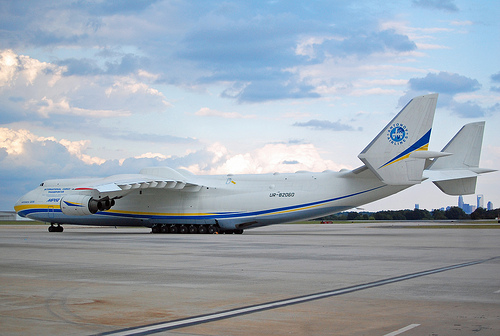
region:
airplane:
[29, 151, 368, 241]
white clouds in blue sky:
[5, 10, 67, 52]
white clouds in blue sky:
[16, 45, 90, 134]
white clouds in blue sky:
[13, 103, 97, 169]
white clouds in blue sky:
[98, 110, 184, 175]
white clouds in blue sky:
[115, 42, 195, 92]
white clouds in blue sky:
[213, 19, 303, 90]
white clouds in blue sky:
[200, 101, 273, 143]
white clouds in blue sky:
[251, 87, 353, 155]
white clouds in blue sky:
[299, 14, 419, 71]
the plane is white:
[17, 104, 493, 264]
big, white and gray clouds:
[69, 29, 368, 191]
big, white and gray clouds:
[132, 114, 294, 196]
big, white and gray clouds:
[22, 67, 133, 223]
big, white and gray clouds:
[286, 28, 463, 117]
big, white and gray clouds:
[43, 45, 141, 134]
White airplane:
[11, 95, 451, 237]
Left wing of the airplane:
[65, 179, 215, 200]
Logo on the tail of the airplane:
[385, 122, 409, 143]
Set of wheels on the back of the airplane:
[148, 222, 245, 237]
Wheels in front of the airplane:
[44, 221, 65, 235]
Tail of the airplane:
[341, 93, 496, 204]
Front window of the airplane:
[37, 181, 47, 189]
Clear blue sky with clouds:
[1, 3, 498, 227]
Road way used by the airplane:
[1, 198, 496, 335]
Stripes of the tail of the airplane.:
[380, 122, 434, 169]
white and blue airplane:
[21, 96, 353, 240]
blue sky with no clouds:
[10, 13, 95, 77]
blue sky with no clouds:
[6, 53, 89, 120]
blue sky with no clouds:
[24, 115, 116, 176]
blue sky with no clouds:
[116, 10, 203, 63]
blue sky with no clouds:
[141, 101, 231, 132]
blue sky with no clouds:
[193, 10, 311, 62]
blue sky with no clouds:
[217, 96, 296, 154]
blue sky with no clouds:
[320, 92, 360, 167]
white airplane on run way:
[30, 110, 376, 252]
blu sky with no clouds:
[7, 12, 117, 87]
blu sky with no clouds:
[19, 65, 88, 115]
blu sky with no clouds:
[23, 124, 112, 177]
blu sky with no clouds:
[158, 20, 250, 84]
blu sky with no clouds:
[267, 31, 361, 86]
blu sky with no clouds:
[70, 95, 192, 151]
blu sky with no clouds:
[107, 31, 224, 134]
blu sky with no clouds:
[299, 24, 388, 113]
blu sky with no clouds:
[46, 40, 197, 147]